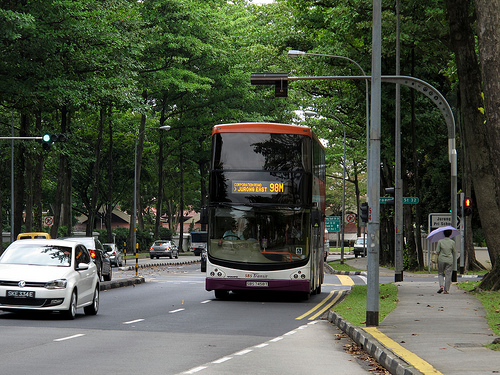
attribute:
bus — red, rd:
[191, 106, 333, 301]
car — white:
[12, 222, 117, 311]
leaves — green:
[166, 27, 225, 87]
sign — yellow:
[227, 177, 288, 194]